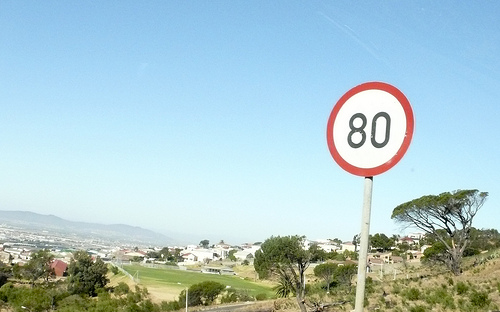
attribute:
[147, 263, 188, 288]
green grass — bright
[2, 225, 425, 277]
houses — distance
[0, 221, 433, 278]
buildings — distance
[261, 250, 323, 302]
trunk — tree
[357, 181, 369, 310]
silverish post — Silverish 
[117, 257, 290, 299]
grass — area 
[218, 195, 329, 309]
trees — middle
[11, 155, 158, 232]
mountain tops — distance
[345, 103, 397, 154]
numbers — black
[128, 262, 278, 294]
grass — green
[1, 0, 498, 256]
sky — blue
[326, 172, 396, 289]
pole — metal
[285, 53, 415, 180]
sign — red, white, black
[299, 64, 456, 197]
sign — route 80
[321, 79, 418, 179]
sign — white area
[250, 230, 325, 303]
tree — small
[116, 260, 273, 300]
grass — green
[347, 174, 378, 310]
pole — gray